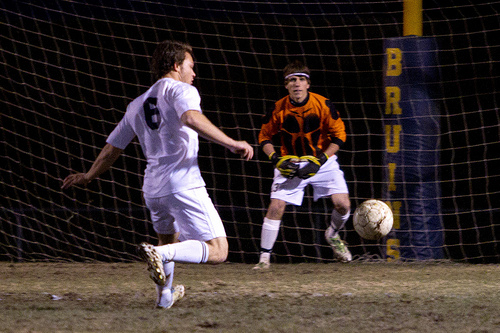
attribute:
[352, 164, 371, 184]
hole — square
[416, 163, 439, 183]
hole — square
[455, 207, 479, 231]
hole — square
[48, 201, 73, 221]
hole — square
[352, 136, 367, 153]
hole — square